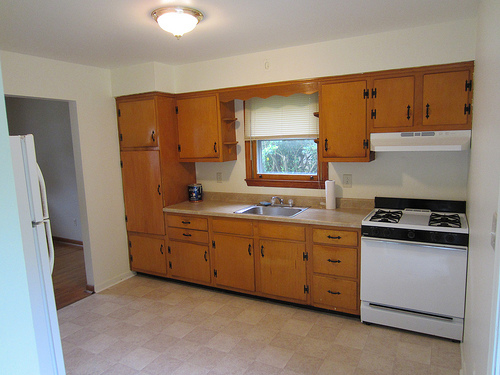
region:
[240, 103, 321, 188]
an open window above a sink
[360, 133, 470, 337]
a stove top and oven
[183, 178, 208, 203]
a coffee machine and supplies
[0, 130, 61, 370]
a small white refrigerater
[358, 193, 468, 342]
a white colored stove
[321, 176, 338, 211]
a roll of white paper towels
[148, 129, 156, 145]
a black cabinet handle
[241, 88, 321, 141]
beige colored window blinds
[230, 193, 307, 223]
a stainless steel sink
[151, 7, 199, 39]
the light is on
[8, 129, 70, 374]
the refrigerator is white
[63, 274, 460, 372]
the floors are made of tiles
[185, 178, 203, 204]
a blue tin can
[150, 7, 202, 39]
the light is attached to the ceiling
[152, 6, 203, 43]
Light on ceiling is lit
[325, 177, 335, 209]
White paper roll on counter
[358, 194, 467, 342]
Black and white stove in the kitchen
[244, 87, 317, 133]
White blinds over window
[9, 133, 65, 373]
White fridge in the kitchen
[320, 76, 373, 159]
Brown cabinet above the stove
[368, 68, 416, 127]
Brown cabinet above the stove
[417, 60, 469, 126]
Brown cabinet above the stove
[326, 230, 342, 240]
Black knob on brown drawer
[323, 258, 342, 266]
Black knob on brown drawer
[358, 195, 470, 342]
black and white oven and stove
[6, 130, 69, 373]
white two door refrigerator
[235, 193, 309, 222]
single basin metal sink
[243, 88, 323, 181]
blinds half covering a window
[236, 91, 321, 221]
window above a kitchen sink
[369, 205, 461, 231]
four burners on a stove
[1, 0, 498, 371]
kitchen with white walls and wood cabinets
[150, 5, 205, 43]
bright ceiling light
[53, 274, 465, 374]
beige colored laminate kitchen floor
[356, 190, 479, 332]
White and black gas stove.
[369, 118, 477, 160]
Stove hood exhaust under cabinets.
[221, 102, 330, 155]
Small shelves alongside window.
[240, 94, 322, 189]
White pull down shade for window.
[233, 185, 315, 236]
Stainless steele sink and faucets.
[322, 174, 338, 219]
Paper towel roll sits countertop.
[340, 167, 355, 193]
Electrical switch for garbage disposal.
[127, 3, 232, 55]
Bright dome light ceiling overhead.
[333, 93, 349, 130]
CABINETS MADE OF WOOD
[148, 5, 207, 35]
LIGHT IN THE CEILING